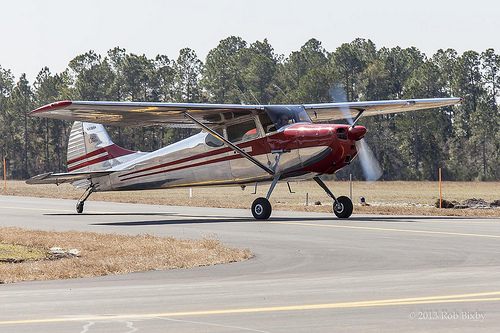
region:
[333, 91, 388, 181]
Metal propeller on front of plane.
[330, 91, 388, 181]
Spinning propeller on front of plane.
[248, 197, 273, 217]
Small black tire on airplane.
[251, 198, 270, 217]
Landing gear tire on airplane.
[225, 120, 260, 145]
Small window on airplane.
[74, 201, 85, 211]
Small rear tile on airplane.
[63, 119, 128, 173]
Tail wing on an airplane.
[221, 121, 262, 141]
Clear window on front of airplane.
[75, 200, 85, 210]
Tiny wheel on the back of plane.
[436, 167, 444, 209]
Orange post on a runway.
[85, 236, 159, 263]
parched brown grass on the side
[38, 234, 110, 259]
white stone in the grass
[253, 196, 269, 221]
white trim in wheel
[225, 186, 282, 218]
black wheel on plane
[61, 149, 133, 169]
red stripe on tail of plane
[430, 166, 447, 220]
orange post in the ground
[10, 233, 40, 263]
small section of green grass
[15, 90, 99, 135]
red edge on wing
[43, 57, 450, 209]
old fashioned plane on the runway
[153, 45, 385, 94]
forest of green trees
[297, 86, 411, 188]
Plane propeller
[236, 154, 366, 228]
Plane landing gear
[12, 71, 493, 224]
Single engine plane taking off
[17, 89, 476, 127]
Small planes wings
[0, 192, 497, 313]
Small plane airport landing strip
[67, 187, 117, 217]
Rear landing gear on small plane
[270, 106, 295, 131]
pilot of a single engine plane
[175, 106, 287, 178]
Wing support beam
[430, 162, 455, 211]
Orange safety post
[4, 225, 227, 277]
Dead brown grass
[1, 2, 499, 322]
a small airplane on a runway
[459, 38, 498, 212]
pine trees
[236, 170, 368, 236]
a single engine prop plane wheels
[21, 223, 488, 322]
a runway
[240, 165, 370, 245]
a single engine prop plane landing gear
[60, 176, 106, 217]
a single engine prop plane tail wheel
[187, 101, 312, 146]
a single engine prop plane cockpit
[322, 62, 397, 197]
a single engine prop plane propellar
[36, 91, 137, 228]
a single engine prop plane tail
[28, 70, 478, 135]
a single engine prop plane wing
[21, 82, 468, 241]
small plane on the runway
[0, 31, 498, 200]
line of trees near an airport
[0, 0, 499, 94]
clear light colored sky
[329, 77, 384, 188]
propeller in motion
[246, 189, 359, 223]
front wheels on the ground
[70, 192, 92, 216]
back wheel on the ground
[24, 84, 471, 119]
top wing of the plane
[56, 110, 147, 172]
tail of a small airplane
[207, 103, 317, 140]
cockpit of a small plane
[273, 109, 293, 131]
pilot in the cockpit